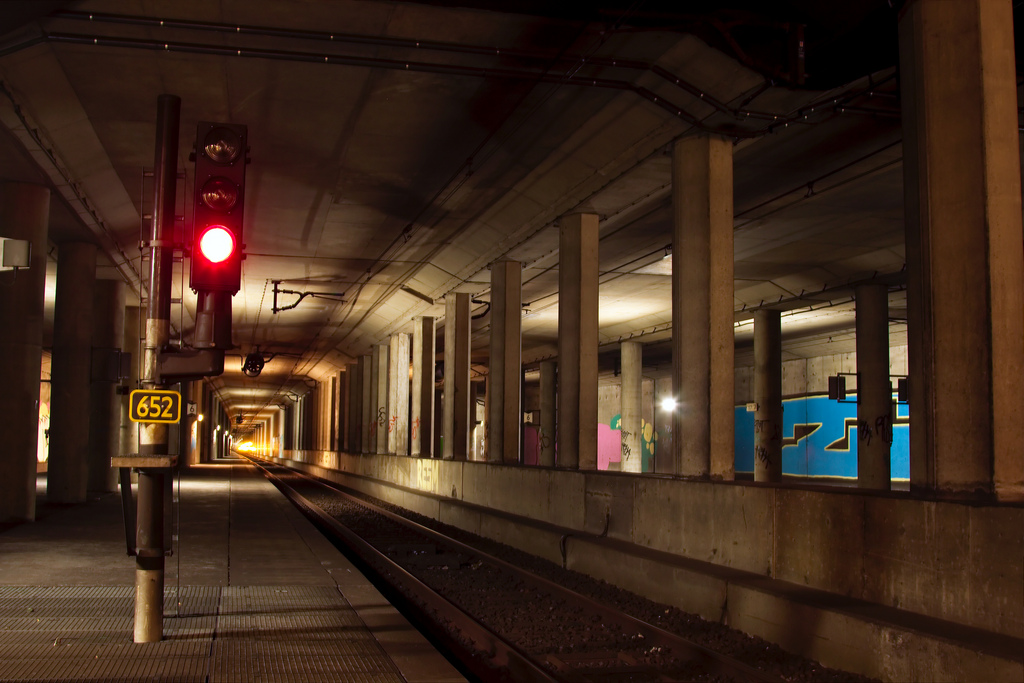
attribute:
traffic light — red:
[177, 106, 258, 303]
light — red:
[177, 207, 247, 288]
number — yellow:
[125, 382, 177, 422]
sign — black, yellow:
[123, 383, 186, 425]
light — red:
[197, 223, 236, 265]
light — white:
[657, 392, 679, 414]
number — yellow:
[134, 390, 152, 417]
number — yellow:
[143, 394, 161, 418]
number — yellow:
[154, 392, 178, 418]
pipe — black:
[3, 27, 900, 140]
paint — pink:
[595, 418, 624, 468]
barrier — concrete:
[266, 443, 982, 679]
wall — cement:
[513, 310, 915, 483]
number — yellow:
[147, 394, 161, 418]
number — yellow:
[160, 392, 176, 418]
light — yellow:
[229, 439, 277, 453]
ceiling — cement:
[5, 3, 909, 434]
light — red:
[205, 219, 262, 313]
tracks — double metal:
[205, 446, 705, 609]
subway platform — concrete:
[114, 433, 478, 606]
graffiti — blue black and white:
[713, 341, 936, 493]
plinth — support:
[24, 222, 154, 501]